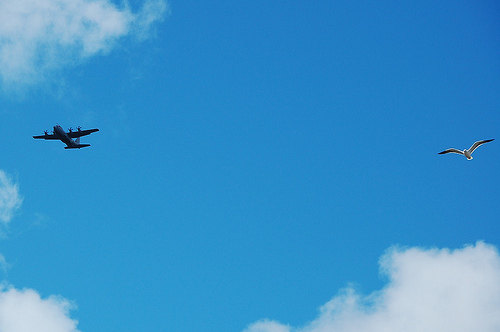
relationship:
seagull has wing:
[435, 135, 497, 166] [440, 147, 464, 160]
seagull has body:
[435, 135, 497, 166] [461, 148, 474, 162]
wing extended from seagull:
[440, 147, 464, 160] [435, 135, 497, 166]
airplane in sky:
[30, 118, 103, 152] [3, 3, 495, 330]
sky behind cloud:
[3, 3, 495, 330] [237, 238, 494, 331]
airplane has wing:
[30, 118, 103, 152] [64, 128, 98, 141]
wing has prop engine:
[64, 128, 98, 141] [67, 126, 74, 133]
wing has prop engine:
[64, 128, 98, 141] [75, 124, 82, 131]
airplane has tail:
[30, 118, 103, 152] [63, 137, 88, 149]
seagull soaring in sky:
[435, 135, 497, 166] [3, 3, 495, 330]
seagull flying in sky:
[435, 135, 497, 166] [3, 3, 495, 330]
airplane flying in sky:
[30, 118, 103, 152] [3, 3, 495, 330]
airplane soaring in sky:
[30, 118, 103, 152] [3, 3, 495, 330]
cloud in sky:
[237, 238, 494, 331] [3, 3, 495, 330]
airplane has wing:
[30, 118, 103, 152] [440, 147, 464, 160]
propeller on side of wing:
[65, 125, 73, 132] [64, 128, 98, 141]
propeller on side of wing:
[76, 124, 84, 131] [64, 128, 98, 141]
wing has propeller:
[33, 133, 58, 142] [41, 128, 49, 136]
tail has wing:
[63, 137, 88, 149] [78, 143, 89, 148]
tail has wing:
[63, 137, 88, 149] [64, 146, 74, 150]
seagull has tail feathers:
[435, 135, 497, 166] [465, 156, 474, 162]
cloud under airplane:
[237, 238, 494, 331] [30, 118, 103, 152]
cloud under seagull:
[237, 238, 494, 331] [435, 135, 497, 166]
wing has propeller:
[64, 128, 98, 141] [65, 125, 73, 132]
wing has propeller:
[64, 128, 98, 141] [76, 124, 84, 131]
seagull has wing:
[435, 135, 497, 166] [469, 138, 494, 156]